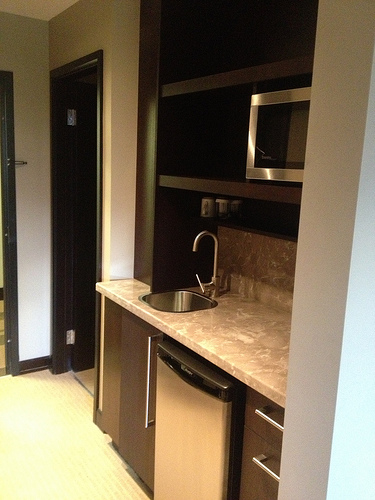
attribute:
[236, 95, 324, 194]
microwave — silver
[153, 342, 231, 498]
dishwasher — silver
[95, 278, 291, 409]
counter top — beige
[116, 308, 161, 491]
cabinet — brown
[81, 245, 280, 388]
countertop — marble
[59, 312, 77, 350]
hinge — silver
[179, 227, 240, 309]
faucet — curved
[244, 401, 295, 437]
handle — silver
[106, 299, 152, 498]
door — wooden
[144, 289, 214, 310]
sink basin — silver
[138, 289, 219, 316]
sink — silver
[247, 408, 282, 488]
handles — silver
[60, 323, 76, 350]
hinge — metal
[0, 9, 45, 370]
wall — white